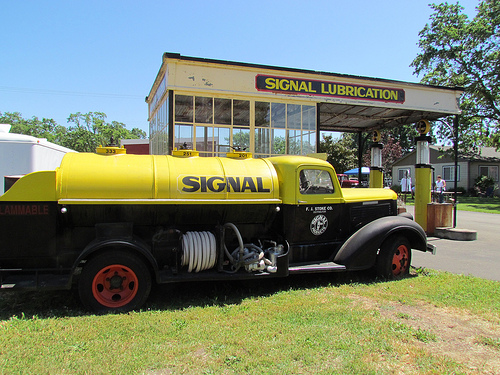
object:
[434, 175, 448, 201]
woman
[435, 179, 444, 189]
shirt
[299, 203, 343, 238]
white logo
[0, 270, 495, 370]
grass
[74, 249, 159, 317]
rims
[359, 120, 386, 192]
gas pump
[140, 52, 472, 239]
station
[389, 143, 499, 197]
house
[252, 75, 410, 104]
sign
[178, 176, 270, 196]
logo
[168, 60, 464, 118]
wall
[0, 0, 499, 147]
sky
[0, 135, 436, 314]
truck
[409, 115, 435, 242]
pump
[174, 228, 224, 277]
reel hose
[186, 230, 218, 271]
hose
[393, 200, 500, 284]
road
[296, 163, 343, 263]
door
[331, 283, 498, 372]
patch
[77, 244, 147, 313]
wheel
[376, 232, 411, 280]
wheel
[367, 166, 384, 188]
pylon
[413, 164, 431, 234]
pylon